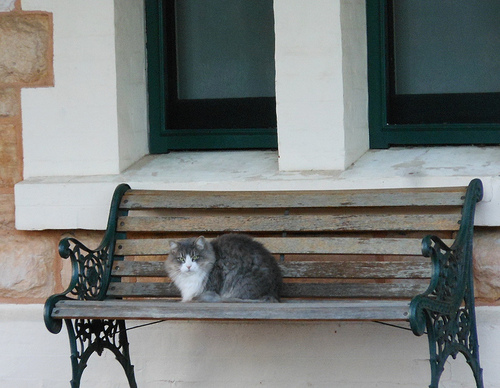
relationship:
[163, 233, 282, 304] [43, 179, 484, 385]
cat on bench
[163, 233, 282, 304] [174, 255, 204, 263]
cat has eye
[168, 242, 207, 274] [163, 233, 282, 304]
face of cat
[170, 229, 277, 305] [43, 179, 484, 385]
cat on bench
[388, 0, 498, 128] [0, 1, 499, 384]
window in building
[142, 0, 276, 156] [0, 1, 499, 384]
window in building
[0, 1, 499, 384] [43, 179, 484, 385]
building behind bench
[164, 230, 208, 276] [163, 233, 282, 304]
head of cat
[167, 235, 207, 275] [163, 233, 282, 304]
head of cat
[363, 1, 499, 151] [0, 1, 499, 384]
window on building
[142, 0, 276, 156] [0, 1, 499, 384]
window on building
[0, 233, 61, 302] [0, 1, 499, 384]
block from building